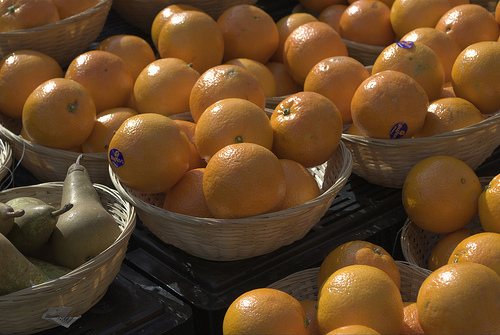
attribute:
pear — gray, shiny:
[33, 168, 113, 257]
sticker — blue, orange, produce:
[97, 149, 147, 183]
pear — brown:
[46, 159, 128, 273]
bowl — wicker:
[0, 177, 138, 333]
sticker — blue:
[382, 118, 410, 142]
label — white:
[44, 306, 91, 333]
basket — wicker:
[1, 178, 139, 333]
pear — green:
[47, 149, 127, 268]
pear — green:
[1, 229, 60, 299]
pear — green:
[2, 192, 73, 255]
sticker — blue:
[105, 146, 130, 172]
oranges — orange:
[104, 65, 344, 219]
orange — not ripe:
[368, 36, 444, 109]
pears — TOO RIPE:
[9, 160, 112, 271]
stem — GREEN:
[66, 99, 78, 114]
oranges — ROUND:
[121, 18, 449, 313]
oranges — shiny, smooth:
[279, 234, 411, 316]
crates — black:
[145, 196, 452, 314]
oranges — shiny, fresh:
[107, 95, 395, 225]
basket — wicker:
[109, 180, 375, 253]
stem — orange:
[63, 96, 82, 118]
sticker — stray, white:
[33, 306, 77, 333]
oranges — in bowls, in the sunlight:
[11, 9, 486, 323]